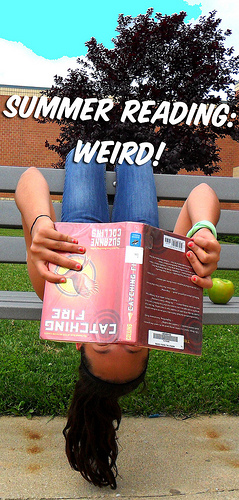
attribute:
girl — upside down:
[62, 132, 161, 405]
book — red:
[44, 309, 118, 338]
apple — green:
[206, 274, 237, 308]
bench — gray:
[159, 175, 233, 200]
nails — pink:
[54, 226, 91, 279]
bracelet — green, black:
[14, 209, 213, 258]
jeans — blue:
[58, 139, 163, 224]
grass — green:
[12, 343, 65, 408]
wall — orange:
[4, 105, 42, 161]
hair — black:
[44, 375, 134, 484]